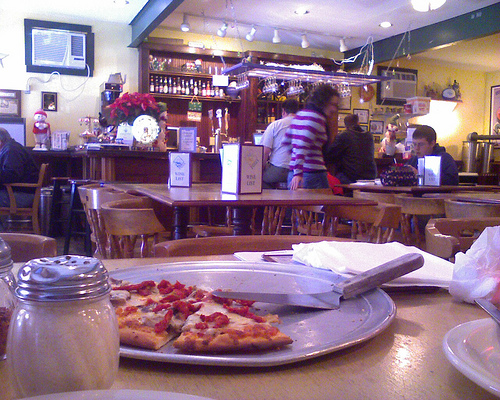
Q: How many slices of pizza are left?
A: 3.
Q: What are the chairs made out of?
A: Wood.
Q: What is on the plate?
A: Pizza.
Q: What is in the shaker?
A: Parmesan cheese.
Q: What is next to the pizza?
A: Pizza spatula.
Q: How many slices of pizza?
A: 3.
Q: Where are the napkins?
A: By the plate.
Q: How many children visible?
A: 0.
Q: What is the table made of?
A: Wood.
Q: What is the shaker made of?
A: Glass.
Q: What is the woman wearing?
A: Striped shirt.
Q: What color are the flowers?
A: Red.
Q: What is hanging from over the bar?
A: Glasses.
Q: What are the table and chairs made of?
A: Wood.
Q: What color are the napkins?
A: White.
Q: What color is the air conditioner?
A: White.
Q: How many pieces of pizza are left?
A: 3.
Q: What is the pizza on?
A: Pan.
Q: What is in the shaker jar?
A: Parmesan cheese.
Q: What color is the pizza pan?
A: Silver.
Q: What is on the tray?
A: Pizza.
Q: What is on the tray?
A: A silver spatula.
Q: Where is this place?
A: Bar.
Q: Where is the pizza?
A: On table.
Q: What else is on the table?
A: Parmesan cheese.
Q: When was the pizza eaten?
A: During the day.